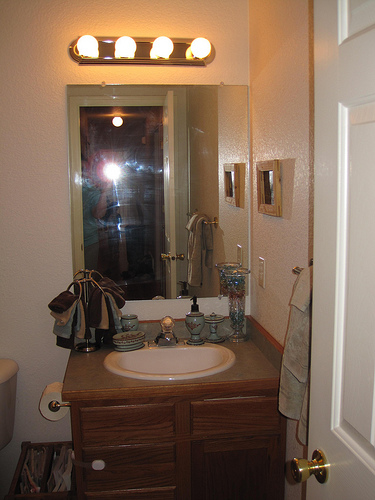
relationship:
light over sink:
[69, 35, 215, 67] [104, 339, 236, 381]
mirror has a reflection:
[66, 85, 248, 299] [93, 163, 148, 281]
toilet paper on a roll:
[40, 383, 69, 421] [49, 401, 62, 413]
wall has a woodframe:
[249, 1, 313, 378] [308, 2, 314, 331]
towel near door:
[279, 266, 311, 448] [306, 0, 373, 499]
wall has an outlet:
[249, 1, 313, 378] [256, 258, 266, 290]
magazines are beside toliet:
[14, 446, 74, 493] [0, 359, 20, 449]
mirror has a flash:
[66, 85, 248, 299] [105, 160, 124, 185]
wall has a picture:
[249, 1, 313, 378] [255, 161, 284, 218]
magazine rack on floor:
[8, 442, 75, 498] [8, 498, 110, 499]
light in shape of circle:
[191, 37, 212, 61] [191, 37, 212, 62]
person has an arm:
[93, 173, 146, 277] [94, 185, 111, 219]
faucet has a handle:
[156, 318, 177, 347] [160, 316, 174, 334]